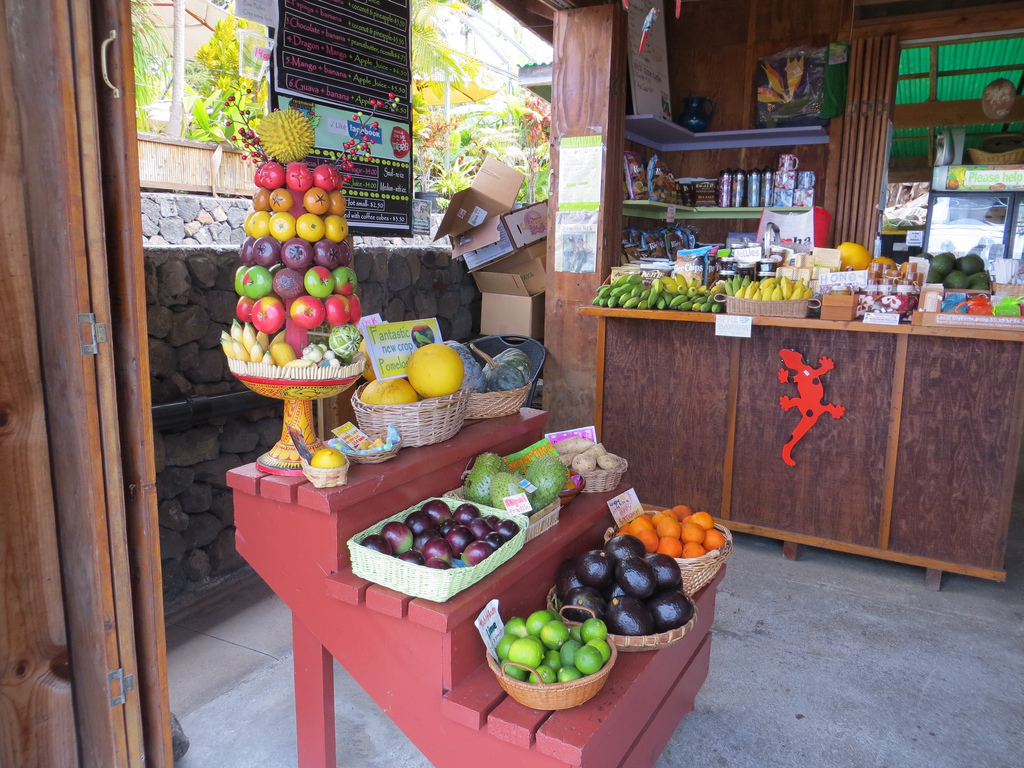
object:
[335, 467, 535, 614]
basket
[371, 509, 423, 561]
mangoes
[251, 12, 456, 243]
prices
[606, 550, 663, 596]
fruits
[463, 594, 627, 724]
bowl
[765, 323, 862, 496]
lizard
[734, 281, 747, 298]
bananas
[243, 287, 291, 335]
fruits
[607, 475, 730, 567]
fruit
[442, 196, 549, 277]
boxes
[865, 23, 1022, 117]
shed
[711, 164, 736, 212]
cans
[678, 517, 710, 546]
oranges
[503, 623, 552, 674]
limes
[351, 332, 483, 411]
grapefruit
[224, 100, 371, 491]
fruit tree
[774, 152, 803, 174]
cups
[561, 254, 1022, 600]
counter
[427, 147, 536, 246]
boxes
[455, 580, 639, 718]
fruit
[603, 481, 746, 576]
fruit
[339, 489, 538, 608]
fruit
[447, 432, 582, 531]
fruit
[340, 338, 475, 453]
fruit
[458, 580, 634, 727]
basket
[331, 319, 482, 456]
basket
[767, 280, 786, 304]
bananas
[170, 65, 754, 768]
display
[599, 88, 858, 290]
shelf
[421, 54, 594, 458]
corner